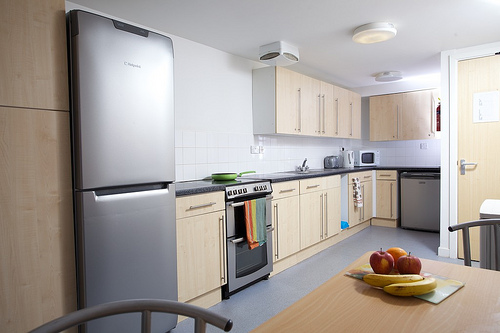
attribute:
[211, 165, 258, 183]
skillet — green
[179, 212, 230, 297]
cabinet door — pale, wooden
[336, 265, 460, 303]
banana — yellow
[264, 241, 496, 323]
table — wooden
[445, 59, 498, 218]
door — wood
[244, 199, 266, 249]
towel — multicolor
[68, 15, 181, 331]
refrigerator — stainless steel, large, stainless, steel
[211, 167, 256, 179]
skillet — green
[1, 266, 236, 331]
chair — silver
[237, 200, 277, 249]
towel — striped, dish, hanging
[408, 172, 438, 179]
handle — black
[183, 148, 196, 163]
tile — square, white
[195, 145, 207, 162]
tile — square, white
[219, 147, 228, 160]
tile — square, white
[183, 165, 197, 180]
tile — square, white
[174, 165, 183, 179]
tile — square, white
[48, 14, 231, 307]
refrigerator — stainless, steel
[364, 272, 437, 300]
bananas — yellow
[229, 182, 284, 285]
stove — stainless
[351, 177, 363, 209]
towel — hanging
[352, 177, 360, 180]
handle — drawer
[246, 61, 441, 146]
cabinets — light, brown, wooden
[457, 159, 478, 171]
handle — silver